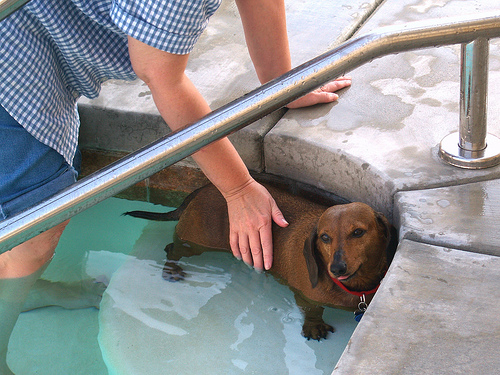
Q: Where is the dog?
A: In a pool.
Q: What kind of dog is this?
A: A doxie.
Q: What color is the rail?
A: Silver.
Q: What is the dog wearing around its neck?
A: A collar.